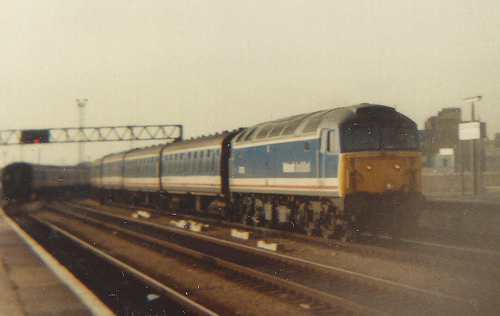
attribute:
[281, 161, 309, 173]
text — White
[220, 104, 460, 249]
train —  side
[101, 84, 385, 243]
train — passenger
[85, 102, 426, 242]
train — side, yellow, blue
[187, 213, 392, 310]
tracks — steel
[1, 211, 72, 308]
platform —  edge 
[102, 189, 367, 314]
tracks — Train, steel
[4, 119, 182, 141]
object — Metal 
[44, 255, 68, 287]
line — White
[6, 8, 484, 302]
picture — decades ago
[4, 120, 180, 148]
object — Metal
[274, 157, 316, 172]
words —  side